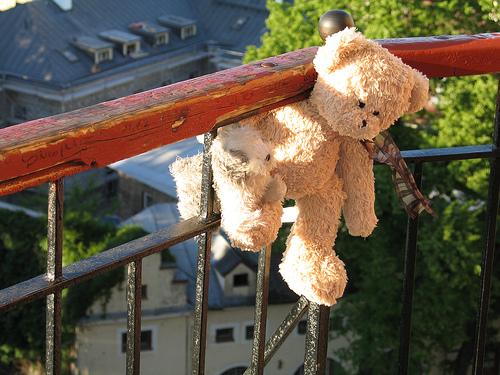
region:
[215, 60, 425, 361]
cute white bear hanged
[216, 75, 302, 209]
a stuffed toy is stuck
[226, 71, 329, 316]
a stuffed toy is stuck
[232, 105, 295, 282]
a stuffed toy is stuck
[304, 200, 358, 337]
a stuffed toy is stuck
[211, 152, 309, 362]
a stuffed toy is stuck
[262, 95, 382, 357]
a stuffed toy is stuck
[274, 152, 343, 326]
a stuffed toy is stuck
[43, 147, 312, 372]
the railings are black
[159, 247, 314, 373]
the railings are black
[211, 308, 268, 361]
the railings are black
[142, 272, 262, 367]
the railings are black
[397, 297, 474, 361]
the railings are black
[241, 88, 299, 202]
a white stuffed toy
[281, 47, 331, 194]
a white stuffed toy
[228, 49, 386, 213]
a white stuffed toy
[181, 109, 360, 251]
a white stuffed toy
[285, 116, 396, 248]
a white stuffed toy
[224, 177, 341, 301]
a white stuffed toy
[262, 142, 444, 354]
a white stuffed toy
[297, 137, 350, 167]
Teddy bear is brown.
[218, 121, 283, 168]
Teddy bear has an animal.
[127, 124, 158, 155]
The board is red.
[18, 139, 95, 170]
Writing on the board.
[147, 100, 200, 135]
Paint coming off the board.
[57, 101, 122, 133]
The board is discolored.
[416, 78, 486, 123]
The tree is green.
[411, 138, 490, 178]
The gate is black.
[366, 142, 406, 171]
The bear is wearing a scarf.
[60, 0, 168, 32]
The roof is grey.